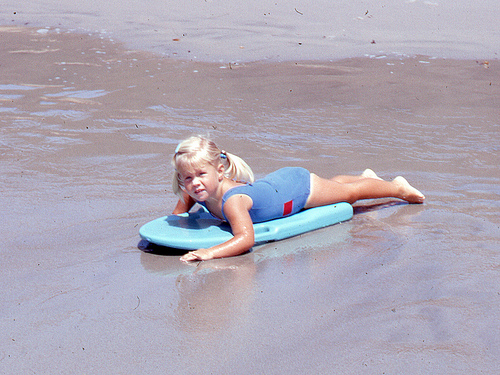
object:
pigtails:
[212, 150, 254, 184]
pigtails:
[171, 170, 184, 204]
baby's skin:
[164, 134, 427, 262]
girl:
[150, 133, 427, 262]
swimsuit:
[204, 165, 313, 222]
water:
[1, 1, 499, 374]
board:
[136, 197, 354, 252]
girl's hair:
[170, 136, 252, 205]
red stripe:
[280, 200, 296, 216]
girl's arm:
[210, 197, 255, 259]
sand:
[1, 0, 499, 60]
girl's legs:
[307, 175, 391, 204]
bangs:
[175, 152, 211, 175]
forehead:
[176, 154, 211, 176]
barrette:
[218, 151, 229, 160]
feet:
[384, 176, 427, 204]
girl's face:
[178, 155, 226, 203]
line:
[303, 171, 313, 210]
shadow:
[132, 240, 186, 258]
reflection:
[164, 201, 229, 234]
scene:
[1, 0, 500, 374]